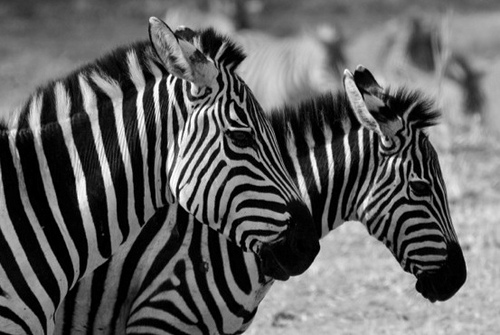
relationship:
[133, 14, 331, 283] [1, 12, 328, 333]
head of zebra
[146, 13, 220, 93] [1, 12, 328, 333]
ear of zebra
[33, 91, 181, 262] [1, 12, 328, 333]
neck of zebra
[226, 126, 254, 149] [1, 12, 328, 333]
eye of zebra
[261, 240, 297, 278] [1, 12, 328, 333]
mouth of zebra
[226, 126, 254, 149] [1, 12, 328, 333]
eye of a zebra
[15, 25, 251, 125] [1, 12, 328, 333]
mane of zebra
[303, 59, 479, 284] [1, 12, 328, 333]
head of zebra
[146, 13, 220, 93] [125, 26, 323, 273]
ear of zebra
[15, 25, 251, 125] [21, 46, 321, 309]
mane of zebra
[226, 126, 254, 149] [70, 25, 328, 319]
eye of a zebra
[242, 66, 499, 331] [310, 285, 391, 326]
grass of ground